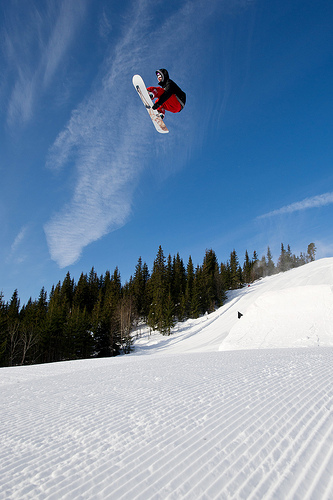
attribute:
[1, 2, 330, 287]
sky — blue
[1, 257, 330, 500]
ground — snow, groomed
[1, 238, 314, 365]
trees — green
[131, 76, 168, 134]
board — white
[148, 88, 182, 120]
pants — red